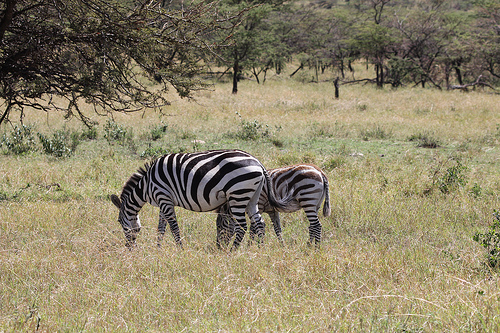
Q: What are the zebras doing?
A: Eating grass.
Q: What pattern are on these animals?
A: Black and white stripes.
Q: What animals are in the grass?
A: Zebras.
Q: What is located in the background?
A: Trees.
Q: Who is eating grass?
A: The zebras.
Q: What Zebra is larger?
A: The closer zebra.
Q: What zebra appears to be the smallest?
A: The one in the back.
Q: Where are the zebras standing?
A: In a field.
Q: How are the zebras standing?
A: Next to each other.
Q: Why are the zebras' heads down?
A: Grazing.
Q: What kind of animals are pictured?
A: Zebras.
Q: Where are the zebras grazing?
A: Field.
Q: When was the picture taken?
A: During the daytime.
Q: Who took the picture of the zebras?
A: A wildlife photographer.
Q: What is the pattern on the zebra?
A: Black and white stripes.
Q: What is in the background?
A: Trees.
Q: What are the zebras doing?
A: Grazing.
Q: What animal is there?
A: Zebras.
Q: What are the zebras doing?
A: Grazing.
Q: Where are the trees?
A: Background.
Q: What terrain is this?
A: Grassland.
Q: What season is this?
A: Summer.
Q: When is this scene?
A: Afternoon.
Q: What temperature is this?
A: 75.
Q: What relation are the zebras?
A: Mother and child.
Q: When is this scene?
A: Afternoon.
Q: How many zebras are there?
A: Two.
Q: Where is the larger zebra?
A: In front.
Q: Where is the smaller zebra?
A: In back.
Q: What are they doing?
A: Grazing.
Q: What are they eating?
A: Grass.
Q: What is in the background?
A: Trees.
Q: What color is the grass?
A: Brown.